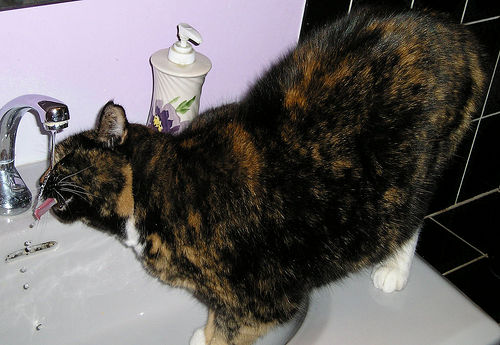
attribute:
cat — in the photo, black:
[23, 1, 492, 344]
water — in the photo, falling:
[50, 132, 58, 164]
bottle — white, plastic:
[145, 25, 213, 136]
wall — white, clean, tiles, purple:
[1, 5, 253, 101]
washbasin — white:
[388, 267, 495, 343]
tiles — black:
[430, 4, 498, 259]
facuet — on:
[1, 92, 66, 222]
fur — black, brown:
[271, 92, 374, 203]